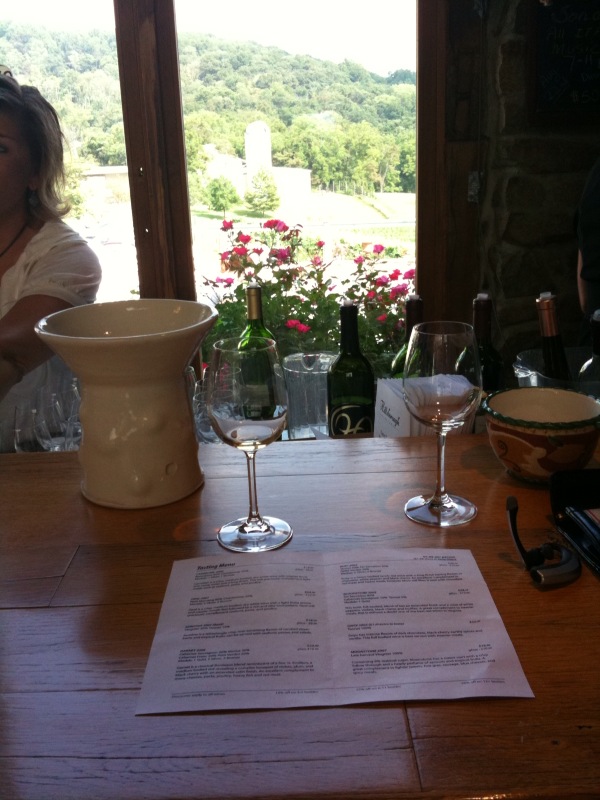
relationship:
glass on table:
[198, 317, 323, 533] [11, 514, 165, 650]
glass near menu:
[198, 317, 323, 533] [158, 554, 534, 716]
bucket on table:
[34, 280, 228, 490] [11, 514, 165, 650]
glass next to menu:
[198, 317, 323, 533] [158, 554, 534, 716]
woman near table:
[0, 88, 102, 319] [11, 514, 165, 650]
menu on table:
[158, 554, 534, 716] [11, 514, 165, 650]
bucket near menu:
[34, 280, 228, 490] [158, 554, 534, 716]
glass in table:
[198, 317, 323, 533] [11, 514, 165, 650]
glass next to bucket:
[198, 317, 323, 533] [34, 280, 228, 490]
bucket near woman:
[34, 280, 228, 490] [0, 88, 102, 319]